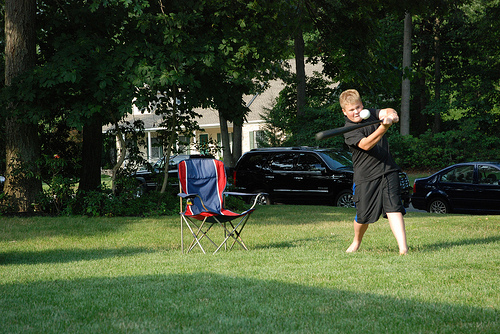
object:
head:
[336, 89, 363, 124]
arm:
[345, 124, 387, 151]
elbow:
[358, 142, 370, 151]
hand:
[378, 107, 397, 125]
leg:
[380, 174, 407, 250]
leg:
[352, 178, 373, 245]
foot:
[345, 242, 363, 254]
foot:
[396, 248, 408, 253]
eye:
[354, 104, 361, 109]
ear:
[339, 108, 349, 119]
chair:
[176, 157, 268, 253]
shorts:
[353, 172, 405, 225]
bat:
[314, 121, 384, 140]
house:
[102, 56, 340, 174]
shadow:
[0, 272, 498, 332]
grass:
[2, 173, 499, 332]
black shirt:
[343, 114, 403, 186]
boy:
[336, 87, 409, 256]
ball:
[359, 107, 370, 122]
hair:
[338, 88, 361, 106]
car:
[411, 163, 499, 214]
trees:
[306, 1, 498, 173]